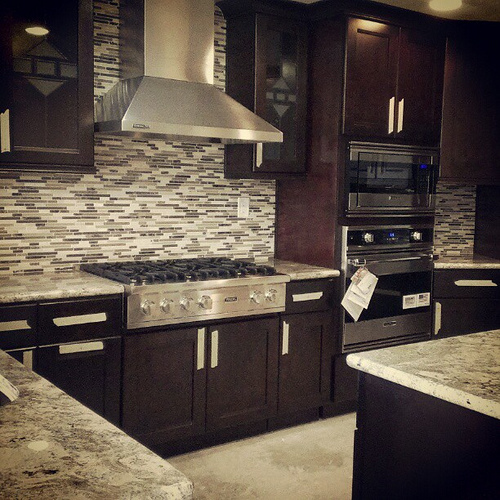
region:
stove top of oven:
[86, 253, 269, 275]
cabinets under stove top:
[131, 316, 327, 421]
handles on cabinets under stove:
[188, 324, 298, 367]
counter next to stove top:
[4, 270, 112, 300]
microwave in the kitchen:
[343, 140, 438, 207]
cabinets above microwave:
[340, 18, 437, 137]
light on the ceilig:
[422, 0, 482, 22]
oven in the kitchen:
[336, 228, 432, 338]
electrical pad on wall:
[232, 188, 255, 223]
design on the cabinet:
[267, 79, 303, 109]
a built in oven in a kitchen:
[345, 141, 438, 343]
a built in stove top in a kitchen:
[85, 249, 290, 319]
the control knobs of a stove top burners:
[139, 293, 216, 318]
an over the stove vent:
[92, 1, 287, 153]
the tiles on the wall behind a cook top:
[127, 185, 198, 245]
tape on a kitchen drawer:
[55, 312, 113, 327]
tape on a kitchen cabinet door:
[193, 324, 210, 372]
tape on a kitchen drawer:
[290, 291, 328, 302]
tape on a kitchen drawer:
[450, 275, 492, 290]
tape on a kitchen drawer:
[2, 317, 33, 338]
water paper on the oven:
[342, 266, 377, 318]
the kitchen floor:
[236, 448, 322, 493]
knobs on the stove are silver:
[137, 292, 222, 308]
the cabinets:
[347, 35, 432, 142]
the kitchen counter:
[5, 420, 105, 485]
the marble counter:
[415, 345, 480, 375]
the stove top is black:
[113, 260, 254, 271]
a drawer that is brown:
[290, 285, 331, 308]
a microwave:
[350, 155, 431, 205]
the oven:
[348, 232, 435, 320]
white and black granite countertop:
[0, 348, 195, 498]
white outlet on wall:
[236, 196, 251, 218]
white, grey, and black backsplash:
[0, 0, 277, 276]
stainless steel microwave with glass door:
[342, 140, 444, 215]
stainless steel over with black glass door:
[341, 219, 436, 354]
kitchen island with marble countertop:
[343, 326, 498, 498]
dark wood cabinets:
[0, 275, 342, 463]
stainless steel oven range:
[82, 254, 289, 331]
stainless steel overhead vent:
[91, 0, 284, 145]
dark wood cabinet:
[321, 2, 448, 146]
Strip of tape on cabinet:
[380, 89, 395, 146]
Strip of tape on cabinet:
[397, 94, 409, 141]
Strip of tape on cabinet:
[290, 288, 329, 304]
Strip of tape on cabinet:
[278, 316, 295, 358]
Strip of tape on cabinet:
[203, 323, 226, 365]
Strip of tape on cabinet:
[189, 324, 205, 381]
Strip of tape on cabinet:
[45, 308, 112, 328]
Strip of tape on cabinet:
[58, 340, 106, 356]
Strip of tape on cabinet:
[0, 103, 20, 161]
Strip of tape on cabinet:
[445, 274, 498, 295]